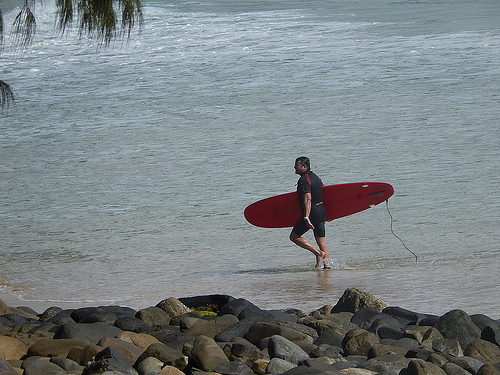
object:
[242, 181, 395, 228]
board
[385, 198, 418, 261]
cable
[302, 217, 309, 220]
watch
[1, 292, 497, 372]
shore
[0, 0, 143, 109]
greenery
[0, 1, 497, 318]
ocean water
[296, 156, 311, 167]
hair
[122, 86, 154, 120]
ocean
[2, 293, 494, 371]
rocks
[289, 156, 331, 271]
male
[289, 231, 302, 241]
knee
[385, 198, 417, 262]
leash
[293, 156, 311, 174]
head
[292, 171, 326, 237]
wetsuit